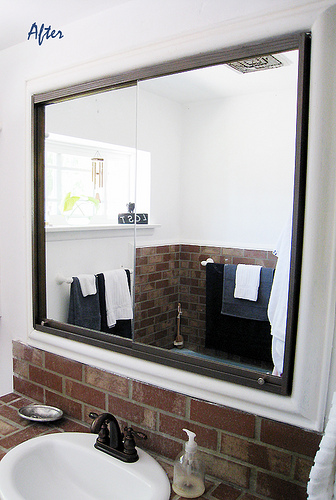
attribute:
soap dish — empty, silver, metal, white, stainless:
[24, 397, 67, 423]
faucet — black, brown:
[91, 410, 143, 458]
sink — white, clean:
[7, 429, 192, 498]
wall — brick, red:
[9, 337, 326, 495]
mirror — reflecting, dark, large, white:
[20, 20, 319, 396]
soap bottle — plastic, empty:
[157, 421, 213, 500]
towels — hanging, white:
[305, 403, 333, 499]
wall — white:
[2, 4, 334, 388]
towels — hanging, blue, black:
[66, 271, 142, 336]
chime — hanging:
[89, 150, 112, 190]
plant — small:
[60, 191, 79, 231]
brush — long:
[168, 290, 193, 353]